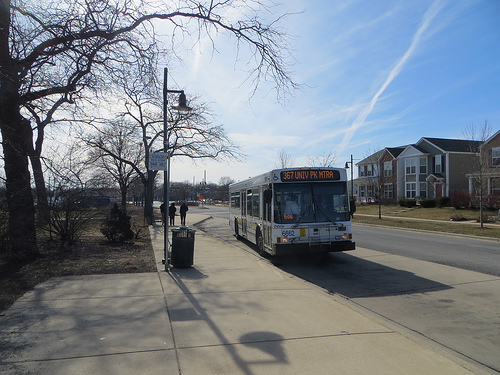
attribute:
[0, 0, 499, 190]
sky — blue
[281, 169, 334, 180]
text — yellow, digital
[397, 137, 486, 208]
house — big, two story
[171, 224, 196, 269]
trash can — metal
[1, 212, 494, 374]
sidewalk — concrete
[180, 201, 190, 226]
person — walking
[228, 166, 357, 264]
bus — moving, white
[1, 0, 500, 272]
trees — bare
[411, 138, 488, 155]
roof — dark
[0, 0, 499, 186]
clouds — thin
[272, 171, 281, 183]
handicap sign — blue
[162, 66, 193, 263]
light post — metal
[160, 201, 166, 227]
person — walking